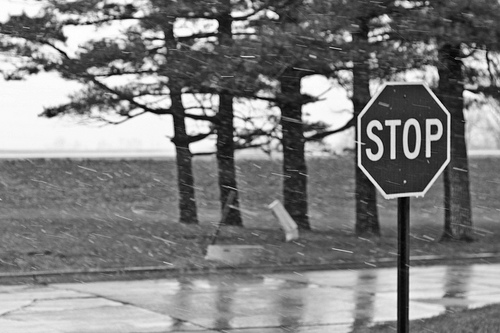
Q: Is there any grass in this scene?
A: Yes, there is grass.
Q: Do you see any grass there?
A: Yes, there is grass.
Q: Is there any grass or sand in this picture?
A: Yes, there is grass.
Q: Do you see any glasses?
A: No, there are no glasses.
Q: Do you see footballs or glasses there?
A: No, there are no glasses or footballs.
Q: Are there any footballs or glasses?
A: No, there are no glasses or footballs.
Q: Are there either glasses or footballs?
A: No, there are no glasses or footballs.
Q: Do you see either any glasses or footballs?
A: No, there are no glasses or footballs.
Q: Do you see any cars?
A: No, there are no cars.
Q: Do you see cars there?
A: No, there are no cars.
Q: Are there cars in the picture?
A: No, there are no cars.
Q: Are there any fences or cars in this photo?
A: No, there are no cars or fences.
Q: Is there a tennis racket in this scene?
A: No, there are no rackets.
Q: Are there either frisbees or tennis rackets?
A: No, there are no tennis rackets or frisbees.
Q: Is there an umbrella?
A: No, there are no umbrellas.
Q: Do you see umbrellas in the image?
A: No, there are no umbrellas.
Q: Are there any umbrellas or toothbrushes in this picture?
A: No, there are no umbrellas or toothbrushes.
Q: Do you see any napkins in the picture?
A: No, there are no napkins.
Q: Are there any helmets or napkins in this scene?
A: No, there are no napkins or helmets.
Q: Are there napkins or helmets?
A: No, there are no napkins or helmets.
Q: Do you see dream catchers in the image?
A: No, there are no dream catchers.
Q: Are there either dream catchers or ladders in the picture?
A: No, there are no dream catchers or ladders.